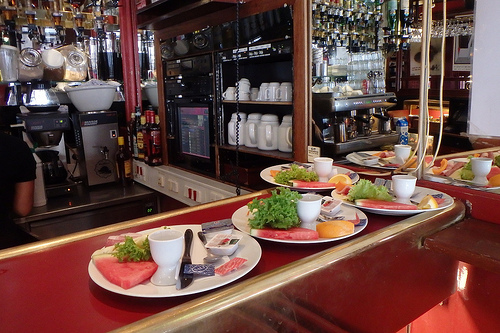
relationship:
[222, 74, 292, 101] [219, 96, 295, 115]
coffee cups on shelf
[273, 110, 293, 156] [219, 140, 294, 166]
water jug on shelf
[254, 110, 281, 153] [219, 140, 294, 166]
water jug on shelf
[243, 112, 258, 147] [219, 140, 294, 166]
water jug on shelf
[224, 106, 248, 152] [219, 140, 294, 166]
water jug on shelf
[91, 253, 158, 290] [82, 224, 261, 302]
sliced watermelon on plate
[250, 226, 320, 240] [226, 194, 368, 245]
watermelon on plate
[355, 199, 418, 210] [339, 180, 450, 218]
watermelon on plate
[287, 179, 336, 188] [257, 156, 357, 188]
watermelon on plate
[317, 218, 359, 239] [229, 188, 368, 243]
orange on plate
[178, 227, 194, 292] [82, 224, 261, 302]
butter knife on plate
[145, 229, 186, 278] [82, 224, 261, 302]
cupe on plate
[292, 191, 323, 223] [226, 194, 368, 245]
cupe on plate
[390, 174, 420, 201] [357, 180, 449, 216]
cupe on plate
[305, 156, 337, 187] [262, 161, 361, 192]
cupe on plate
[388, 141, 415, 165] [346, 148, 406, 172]
cupe on plate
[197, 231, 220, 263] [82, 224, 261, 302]
spoon on plate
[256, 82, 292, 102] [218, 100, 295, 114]
coffee cups on shelf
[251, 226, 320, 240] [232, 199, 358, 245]
watermelon on plate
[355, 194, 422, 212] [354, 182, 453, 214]
watermelon on plate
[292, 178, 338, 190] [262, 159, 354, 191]
watermelon on plate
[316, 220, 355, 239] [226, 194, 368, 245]
orange on a plate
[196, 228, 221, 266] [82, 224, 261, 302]
spoon on a plate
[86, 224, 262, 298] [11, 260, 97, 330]
plate on red counter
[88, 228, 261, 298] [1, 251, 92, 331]
plate on a table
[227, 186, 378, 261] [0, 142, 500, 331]
plate on table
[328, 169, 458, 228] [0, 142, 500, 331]
plate on table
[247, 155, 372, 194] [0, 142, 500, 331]
plate on table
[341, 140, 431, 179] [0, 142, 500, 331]
plate on table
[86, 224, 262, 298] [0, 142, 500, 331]
plate on table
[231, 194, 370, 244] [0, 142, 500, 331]
plate on table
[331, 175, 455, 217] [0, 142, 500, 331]
plate on table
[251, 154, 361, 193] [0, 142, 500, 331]
plate on table